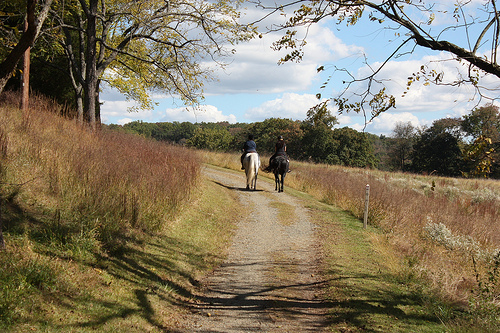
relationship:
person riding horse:
[240, 133, 262, 162] [240, 150, 263, 191]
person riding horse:
[268, 132, 292, 157] [266, 152, 293, 190]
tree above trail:
[256, 2, 499, 125] [229, 196, 320, 333]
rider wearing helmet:
[244, 138, 260, 152] [246, 132, 255, 140]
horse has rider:
[240, 150, 263, 191] [240, 133, 262, 162]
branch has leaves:
[336, 70, 380, 107] [321, 99, 369, 121]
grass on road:
[24, 223, 157, 273] [229, 196, 320, 333]